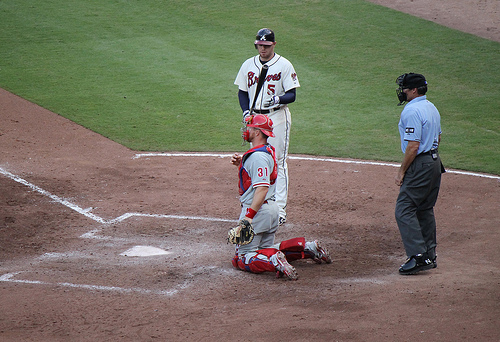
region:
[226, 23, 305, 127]
person is playing baseball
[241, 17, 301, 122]
person is getting ready to bat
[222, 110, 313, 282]
person is on his knees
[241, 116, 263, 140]
person wearing a face mask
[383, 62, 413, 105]
person wearing a face mask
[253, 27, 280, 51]
person wearing a black baseball hat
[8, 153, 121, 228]
white line painted on ground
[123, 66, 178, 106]
short green grassy turf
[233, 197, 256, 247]
glove is left hand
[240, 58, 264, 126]
bat is in right hand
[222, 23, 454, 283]
Three men on baseball field.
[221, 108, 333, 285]
Catcher is on his knees.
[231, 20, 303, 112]
Batter holding bat in his right hand.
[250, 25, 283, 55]
Batter wearing safety helmet.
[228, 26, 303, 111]
Batter wearing shirt with number 5 on it.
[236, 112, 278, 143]
Catcher wearing face mask.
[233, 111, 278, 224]
Catcher has number 31 on shirt sleeve.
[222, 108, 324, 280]
Catcher wearing shin guards.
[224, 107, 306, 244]
Catcher wearing catcher's mitt on left hand.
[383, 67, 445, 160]
The umpire is wearing a face mask.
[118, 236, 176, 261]
home plate on the field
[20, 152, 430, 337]
sand on the baseball field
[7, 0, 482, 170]
grass on the baseball field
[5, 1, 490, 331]
a baseball field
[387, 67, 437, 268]
the umpire of the baseball game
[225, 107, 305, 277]
the catcher of the baseball game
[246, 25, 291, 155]
a baseball player holding a baseball bat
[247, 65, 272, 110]
the baseball bat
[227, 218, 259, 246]
the catchers mitt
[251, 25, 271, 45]
a man with a baseball helmet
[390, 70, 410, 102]
a man with a catchers mask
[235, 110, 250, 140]
a man with a catchers mask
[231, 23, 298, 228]
a player holding a baseball bat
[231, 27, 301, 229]
a baseball player holding a baseball bat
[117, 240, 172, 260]
the diamond of a baseball base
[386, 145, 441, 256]
a man wearing grey pants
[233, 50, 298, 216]
a man in a baseball uniform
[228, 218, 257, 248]
a man with a baseball glove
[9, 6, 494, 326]
a major league baseball game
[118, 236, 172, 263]
home-plate on a baseball field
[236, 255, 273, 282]
the shinguard of a catcher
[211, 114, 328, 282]
the catcher on a baseball team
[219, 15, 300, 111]
a batter preparing to bat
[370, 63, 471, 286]
a major league umpire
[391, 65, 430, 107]
the face mask of an umpire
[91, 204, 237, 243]
the batter's box on a baseball field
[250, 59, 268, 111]
a black wooden baseball bat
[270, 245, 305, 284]
one of the catcher's cleats